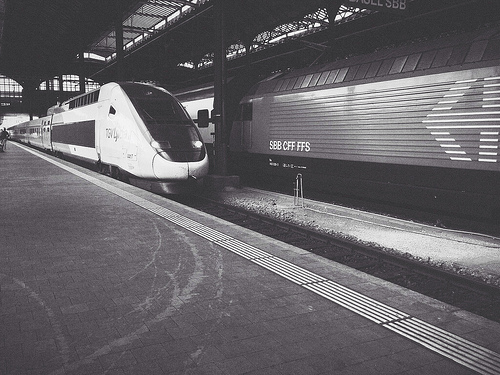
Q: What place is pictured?
A: It is a terminal.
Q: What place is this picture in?
A: It is at the terminal.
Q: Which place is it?
A: It is a terminal.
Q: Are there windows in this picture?
A: Yes, there is a window.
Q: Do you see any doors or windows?
A: Yes, there is a window.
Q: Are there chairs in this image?
A: No, there are no chairs.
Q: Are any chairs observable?
A: No, there are no chairs.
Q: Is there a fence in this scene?
A: No, there are no fences.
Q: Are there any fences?
A: No, there are no fences.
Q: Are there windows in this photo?
A: Yes, there is a window.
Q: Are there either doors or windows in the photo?
A: Yes, there is a window.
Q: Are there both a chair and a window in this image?
A: No, there is a window but no chairs.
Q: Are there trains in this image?
A: Yes, there is a train.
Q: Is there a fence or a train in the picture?
A: Yes, there is a train.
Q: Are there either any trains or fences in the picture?
A: Yes, there is a train.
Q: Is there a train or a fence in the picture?
A: Yes, there is a train.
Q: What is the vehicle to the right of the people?
A: The vehicle is a train.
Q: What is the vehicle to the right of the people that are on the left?
A: The vehicle is a train.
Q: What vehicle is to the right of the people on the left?
A: The vehicle is a train.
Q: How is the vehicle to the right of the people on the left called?
A: The vehicle is a train.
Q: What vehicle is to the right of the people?
A: The vehicle is a train.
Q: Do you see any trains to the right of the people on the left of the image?
A: Yes, there is a train to the right of the people.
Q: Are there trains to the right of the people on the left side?
A: Yes, there is a train to the right of the people.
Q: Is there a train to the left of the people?
A: No, the train is to the right of the people.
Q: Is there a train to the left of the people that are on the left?
A: No, the train is to the right of the people.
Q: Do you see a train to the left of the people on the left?
A: No, the train is to the right of the people.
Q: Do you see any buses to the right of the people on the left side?
A: No, there is a train to the right of the people.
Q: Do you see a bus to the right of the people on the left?
A: No, there is a train to the right of the people.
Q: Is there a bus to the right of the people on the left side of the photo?
A: No, there is a train to the right of the people.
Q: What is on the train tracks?
A: The train is on the train tracks.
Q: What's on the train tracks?
A: The train is on the train tracks.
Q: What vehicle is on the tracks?
A: The vehicle is a train.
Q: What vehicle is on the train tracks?
A: The vehicle is a train.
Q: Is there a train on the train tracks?
A: Yes, there is a train on the train tracks.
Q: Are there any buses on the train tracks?
A: No, there is a train on the train tracks.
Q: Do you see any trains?
A: Yes, there is a train.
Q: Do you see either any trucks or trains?
A: Yes, there is a train.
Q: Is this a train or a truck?
A: This is a train.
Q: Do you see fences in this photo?
A: No, there are no fences.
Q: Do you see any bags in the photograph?
A: No, there are no bags.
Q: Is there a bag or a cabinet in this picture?
A: No, there are no bags or cabinets.